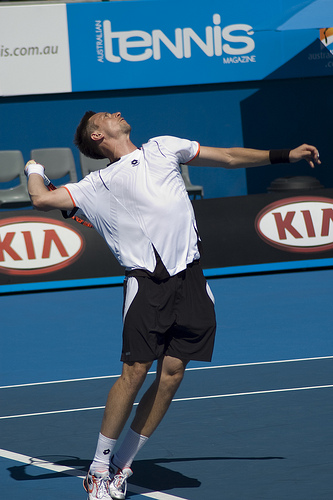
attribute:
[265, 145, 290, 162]
wristband — black